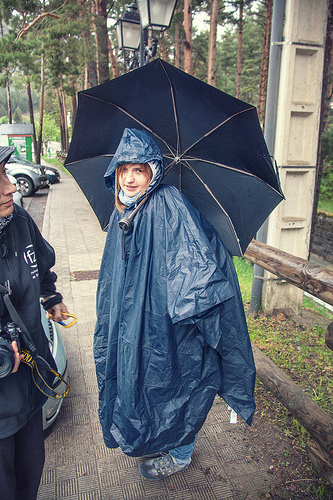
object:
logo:
[23, 243, 40, 281]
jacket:
[0, 201, 63, 439]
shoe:
[138, 453, 194, 484]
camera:
[0, 285, 71, 400]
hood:
[104, 124, 165, 210]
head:
[116, 133, 153, 201]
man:
[0, 147, 77, 499]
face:
[117, 161, 152, 197]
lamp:
[113, 1, 141, 54]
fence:
[244, 236, 332, 310]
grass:
[238, 264, 249, 284]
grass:
[45, 156, 55, 164]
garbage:
[227, 404, 237, 426]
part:
[276, 377, 293, 405]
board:
[250, 339, 332, 455]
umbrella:
[62, 57, 287, 262]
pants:
[0, 405, 47, 499]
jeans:
[168, 433, 198, 464]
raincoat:
[93, 127, 257, 457]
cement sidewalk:
[58, 203, 85, 281]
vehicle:
[5, 156, 48, 196]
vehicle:
[13, 155, 61, 185]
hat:
[0, 144, 16, 164]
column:
[259, 0, 327, 317]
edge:
[146, 474, 167, 480]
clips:
[246, 0, 284, 318]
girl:
[92, 125, 256, 480]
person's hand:
[45, 302, 71, 324]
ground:
[39, 189, 279, 497]